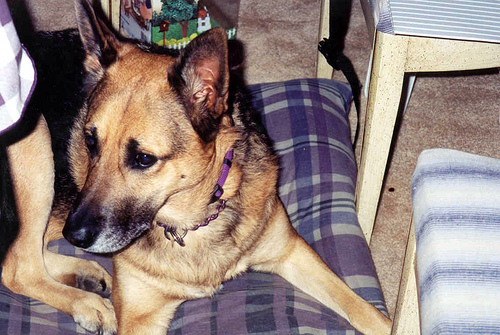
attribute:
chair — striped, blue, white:
[386, 136, 497, 333]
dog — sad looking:
[0, 0, 386, 334]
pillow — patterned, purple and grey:
[385, 135, 498, 332]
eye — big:
[131, 149, 156, 169]